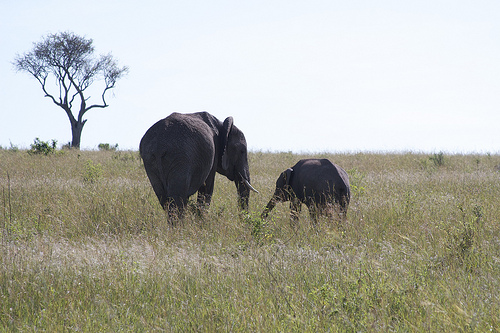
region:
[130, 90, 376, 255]
two elephants walking together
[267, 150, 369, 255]
baby elephant walking through grass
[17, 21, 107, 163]
single tree in the field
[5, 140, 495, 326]
field of tall grass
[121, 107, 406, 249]
baby elephant with parent in grass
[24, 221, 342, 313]
patch of lighter grass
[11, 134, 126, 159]
two bushes near lone tree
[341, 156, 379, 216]
tall weed beside baby elephant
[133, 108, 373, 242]
two elephants looking at eachother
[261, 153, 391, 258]
baby elephant in grass taller then it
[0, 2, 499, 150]
cloud cover in sky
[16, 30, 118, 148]
tree with no leaves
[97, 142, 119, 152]
top of bush on horizon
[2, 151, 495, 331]
ground with tall dried grass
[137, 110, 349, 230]
two elephants in grass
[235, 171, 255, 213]
trunk with white tusk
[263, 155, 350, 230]
young elephant with extended trunk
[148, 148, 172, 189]
tail on back of elephant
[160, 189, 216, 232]
legs obstructed by grass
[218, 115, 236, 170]
ear on elephant head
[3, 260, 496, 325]
a lot of grass in the field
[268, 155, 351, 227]
a baby elephant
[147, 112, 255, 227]
an adult elephant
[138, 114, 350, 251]
two elephants in the field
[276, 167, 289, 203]
the head of the baby elephant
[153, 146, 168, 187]
the tail of the big elephant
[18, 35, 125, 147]
a lonely tree in the field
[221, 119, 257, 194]
the head of the mother elephant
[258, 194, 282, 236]
the baby elephant's trunk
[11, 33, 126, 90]
dry branches of the tree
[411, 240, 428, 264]
part of a grass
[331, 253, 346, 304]
part of a plain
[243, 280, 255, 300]
part of a park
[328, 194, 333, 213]
part of an elephant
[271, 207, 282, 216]
part of a trunk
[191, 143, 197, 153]
body of an elephant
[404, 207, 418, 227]
part of the grass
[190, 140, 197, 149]
side of an elephant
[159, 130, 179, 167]
back of an elephant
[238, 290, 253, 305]
part of the grass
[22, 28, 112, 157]
The tree is bare.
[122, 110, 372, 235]
The elephants are standing.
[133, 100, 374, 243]
The elephants are in the grass.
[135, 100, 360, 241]
The elephants are walking.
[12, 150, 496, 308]
The grass is tall.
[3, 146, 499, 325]
The grass is brown.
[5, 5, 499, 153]
The sky is clear blue.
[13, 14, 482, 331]
The sun is shining.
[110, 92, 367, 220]
The elephants are gray.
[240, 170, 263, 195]
The tusk is white.